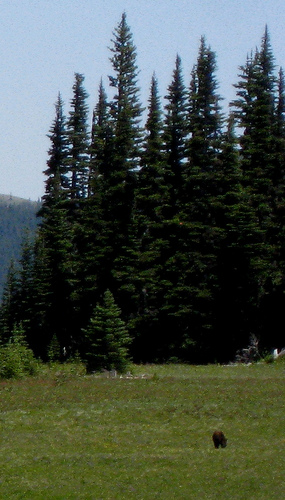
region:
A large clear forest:
[3, 2, 281, 494]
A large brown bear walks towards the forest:
[202, 425, 232, 448]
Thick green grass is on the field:
[30, 383, 184, 498]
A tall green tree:
[70, 286, 146, 373]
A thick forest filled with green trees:
[54, 19, 272, 358]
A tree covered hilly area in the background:
[6, 197, 36, 237]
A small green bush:
[1, 328, 45, 376]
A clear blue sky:
[3, 4, 106, 70]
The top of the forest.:
[60, 24, 278, 164]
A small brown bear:
[183, 420, 231, 453]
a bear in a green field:
[0, 357, 279, 496]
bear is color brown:
[204, 421, 233, 448]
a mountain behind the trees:
[3, 183, 72, 295]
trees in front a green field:
[20, 112, 283, 464]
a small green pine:
[74, 286, 143, 383]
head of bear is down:
[210, 418, 233, 456]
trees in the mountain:
[0, 193, 42, 287]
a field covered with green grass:
[2, 351, 283, 497]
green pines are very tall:
[25, 109, 274, 380]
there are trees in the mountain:
[5, 186, 50, 283]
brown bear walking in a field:
[212, 417, 230, 458]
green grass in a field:
[57, 400, 141, 480]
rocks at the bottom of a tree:
[75, 359, 160, 388]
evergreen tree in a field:
[77, 282, 147, 396]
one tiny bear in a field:
[147, 396, 250, 466]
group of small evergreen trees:
[4, 318, 43, 376]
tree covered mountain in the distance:
[3, 180, 37, 241]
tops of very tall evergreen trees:
[36, 7, 283, 125]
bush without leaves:
[227, 327, 270, 368]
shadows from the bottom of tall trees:
[165, 326, 220, 358]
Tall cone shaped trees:
[0, 8, 282, 371]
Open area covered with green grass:
[0, 362, 284, 499]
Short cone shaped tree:
[75, 285, 142, 385]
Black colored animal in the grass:
[208, 428, 230, 450]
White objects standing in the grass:
[76, 366, 152, 380]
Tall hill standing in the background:
[0, 191, 54, 314]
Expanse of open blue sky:
[0, 0, 284, 203]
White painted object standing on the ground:
[272, 347, 278, 357]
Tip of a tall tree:
[107, 10, 139, 62]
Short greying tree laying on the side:
[226, 329, 264, 367]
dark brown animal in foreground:
[212, 430, 227, 449]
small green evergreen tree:
[84, 289, 131, 376]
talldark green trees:
[2, 10, 284, 362]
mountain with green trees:
[0, 194, 41, 299]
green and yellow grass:
[0, 365, 283, 499]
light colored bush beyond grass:
[228, 333, 261, 365]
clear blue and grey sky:
[0, 0, 284, 201]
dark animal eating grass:
[212, 430, 227, 448]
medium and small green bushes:
[1, 287, 85, 379]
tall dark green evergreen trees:
[1, 7, 283, 362]